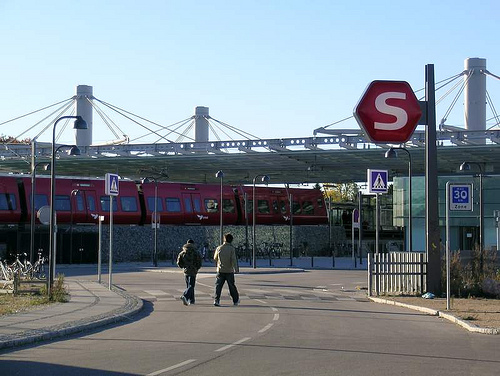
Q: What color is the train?
A: Red.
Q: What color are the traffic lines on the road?
A: White.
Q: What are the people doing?
A: Walking.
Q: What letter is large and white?
A: S.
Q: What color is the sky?
A: Blue.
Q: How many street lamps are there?
A: Two.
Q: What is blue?
A: Sky.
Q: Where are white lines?
A: On the street.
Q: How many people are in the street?
A: Two.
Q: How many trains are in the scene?
A: One.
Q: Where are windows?
A: On a train.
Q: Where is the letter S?
A: On red sign.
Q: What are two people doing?
A: Walking.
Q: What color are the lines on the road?
A: White.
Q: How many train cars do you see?
A: 4.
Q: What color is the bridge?
A: Grey.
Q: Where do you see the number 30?
A: On the sign.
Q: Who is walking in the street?
A: 2 people.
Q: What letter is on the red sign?
A: A capital S.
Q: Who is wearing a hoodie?
A: The man on the left.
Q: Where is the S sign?
A: On the right side of the street.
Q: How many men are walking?
A: 2.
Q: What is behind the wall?
A: A train.